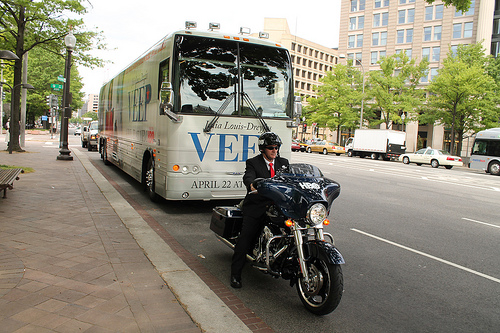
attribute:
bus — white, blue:
[97, 20, 303, 204]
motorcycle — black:
[209, 132, 345, 317]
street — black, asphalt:
[74, 128, 498, 329]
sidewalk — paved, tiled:
[2, 130, 203, 332]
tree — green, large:
[2, 1, 115, 157]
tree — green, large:
[2, 28, 84, 122]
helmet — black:
[258, 131, 284, 154]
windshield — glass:
[173, 33, 295, 119]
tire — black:
[296, 257, 344, 316]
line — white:
[348, 228, 500, 284]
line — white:
[458, 214, 497, 226]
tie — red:
[266, 159, 276, 178]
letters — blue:
[187, 131, 261, 167]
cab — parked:
[400, 142, 463, 171]